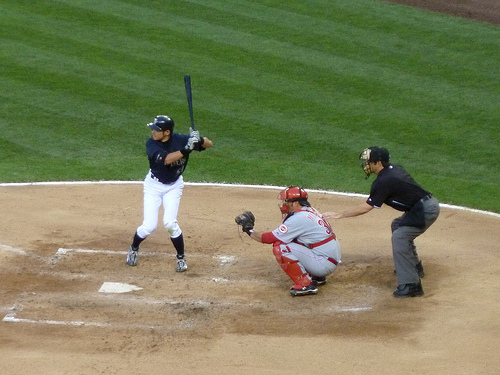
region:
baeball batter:
[126, 72, 204, 274]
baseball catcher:
[216, 173, 341, 295]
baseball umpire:
[346, 123, 443, 291]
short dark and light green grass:
[21, 8, 73, 55]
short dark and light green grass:
[29, 42, 56, 83]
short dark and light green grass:
[27, 105, 69, 142]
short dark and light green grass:
[44, 60, 108, 95]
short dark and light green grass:
[213, 30, 265, 80]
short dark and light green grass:
[260, 35, 351, 69]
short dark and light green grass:
[234, 89, 271, 124]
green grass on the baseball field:
[2, 0, 498, 214]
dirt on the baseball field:
[0, 180, 497, 373]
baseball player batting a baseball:
[128, 72, 214, 276]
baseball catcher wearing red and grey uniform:
[235, 186, 342, 297]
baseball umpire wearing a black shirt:
[335, 145, 439, 297]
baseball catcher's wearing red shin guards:
[270, 242, 309, 291]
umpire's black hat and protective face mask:
[359, 142, 390, 182]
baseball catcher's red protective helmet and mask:
[277, 185, 310, 214]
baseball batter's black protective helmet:
[143, 112, 175, 131]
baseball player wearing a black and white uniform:
[127, 112, 213, 272]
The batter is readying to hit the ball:
[105, 49, 213, 275]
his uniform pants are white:
[125, 159, 190, 286]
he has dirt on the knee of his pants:
[166, 224, 176, 241]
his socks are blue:
[167, 234, 191, 259]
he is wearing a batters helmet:
[132, 106, 180, 136]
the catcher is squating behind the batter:
[230, 157, 360, 296]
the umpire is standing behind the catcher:
[326, 124, 458, 317]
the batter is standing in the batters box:
[26, 227, 237, 352]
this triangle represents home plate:
[90, 276, 145, 302]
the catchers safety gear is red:
[268, 241, 313, 298]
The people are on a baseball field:
[10, 30, 481, 366]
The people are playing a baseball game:
[20, 32, 465, 349]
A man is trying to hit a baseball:
[101, 57, 221, 288]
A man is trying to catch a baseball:
[230, 170, 323, 325]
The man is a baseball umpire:
[343, 135, 459, 331]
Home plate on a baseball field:
[96, 276, 141, 296]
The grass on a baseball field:
[25, 50, 96, 131]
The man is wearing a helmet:
[110, 55, 221, 308]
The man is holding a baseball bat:
[97, 50, 222, 295]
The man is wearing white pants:
[95, 30, 222, 287]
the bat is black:
[182, 63, 206, 150]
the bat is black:
[167, 63, 214, 160]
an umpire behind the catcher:
[232, 107, 472, 364]